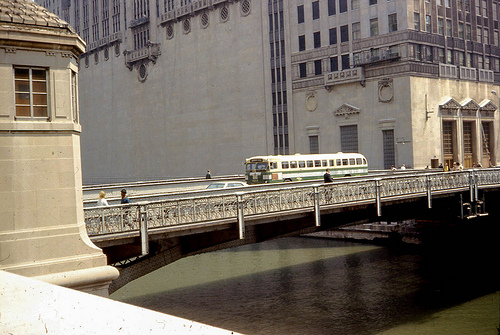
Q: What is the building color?
A: Brown.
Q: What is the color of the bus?
A: White.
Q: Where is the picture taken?
A: Near bridge.